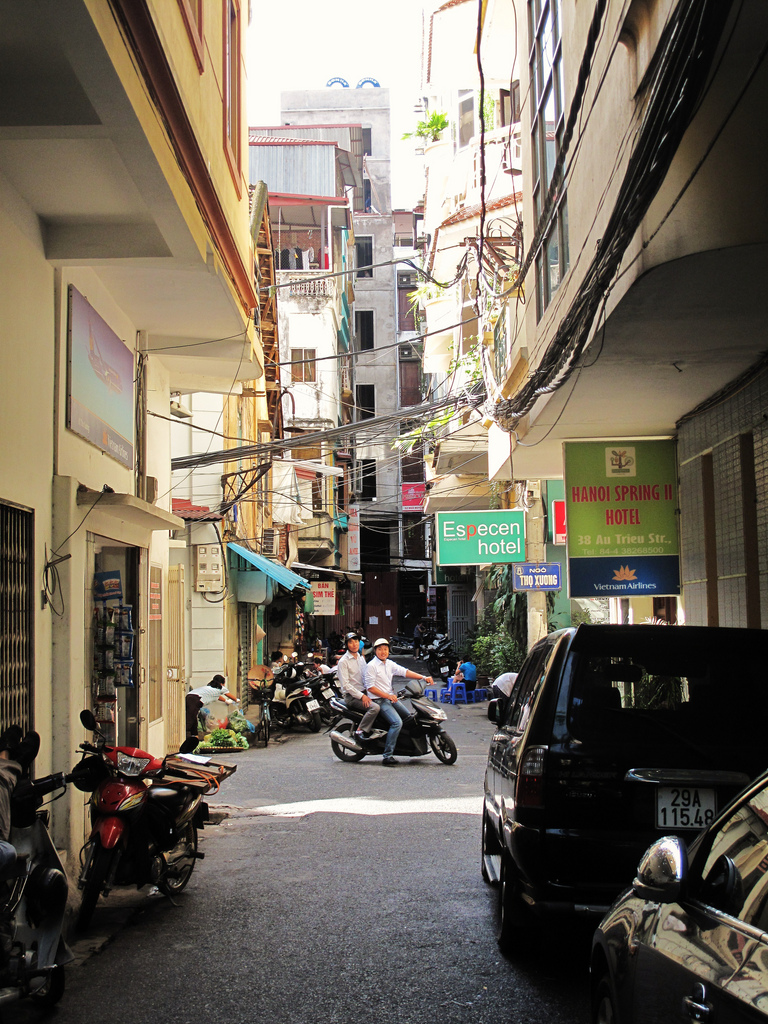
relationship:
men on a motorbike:
[308, 638, 473, 788] [308, 688, 473, 788]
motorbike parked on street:
[35, 748, 211, 862] [35, 748, 488, 862]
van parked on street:
[481, 621, 766, 941] [229, 630, 763, 939]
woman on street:
[166, 659, 240, 739] [115, 568, 541, 1018]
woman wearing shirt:
[457, 653, 486, 697] [454, 657, 484, 684]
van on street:
[477, 614, 765, 935] [96, 616, 611, 1020]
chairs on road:
[421, 681, 487, 707] [208, 620, 509, 997]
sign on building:
[433, 500, 530, 574] [245, 124, 375, 592]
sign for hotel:
[538, 430, 698, 640] [488, 6, 764, 631]